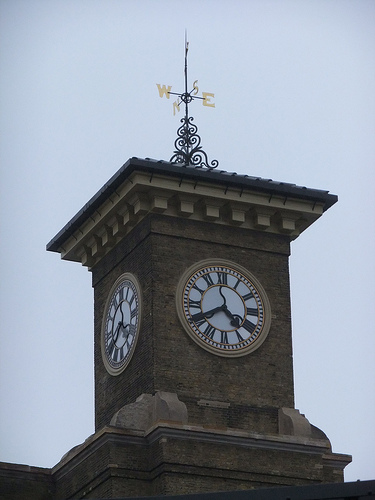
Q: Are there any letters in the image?
A: Yes, there are letters.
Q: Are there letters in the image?
A: Yes, there are letters.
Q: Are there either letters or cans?
A: Yes, there are letters.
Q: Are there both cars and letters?
A: No, there are letters but no cars.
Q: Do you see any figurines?
A: No, there are no figurines.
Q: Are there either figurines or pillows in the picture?
A: No, there are no figurines or pillows.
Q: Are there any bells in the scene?
A: No, there are no bells.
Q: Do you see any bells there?
A: No, there are no bells.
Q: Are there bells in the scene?
A: No, there are no bells.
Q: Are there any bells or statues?
A: No, there are no bells or statues.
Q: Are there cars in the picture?
A: No, there are no cars.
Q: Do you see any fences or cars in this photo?
A: No, there are no cars or fences.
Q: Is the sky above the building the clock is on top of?
A: Yes, the sky is above the building.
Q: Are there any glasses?
A: No, there are no glasses.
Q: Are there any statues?
A: No, there are no statues.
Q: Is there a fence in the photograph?
A: No, there are no fences.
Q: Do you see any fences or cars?
A: No, there are no fences or cars.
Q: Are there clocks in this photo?
A: Yes, there is a clock.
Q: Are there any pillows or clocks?
A: Yes, there is a clock.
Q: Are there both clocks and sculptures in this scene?
A: No, there is a clock but no sculptures.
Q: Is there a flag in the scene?
A: No, there are no flags.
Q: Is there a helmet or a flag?
A: No, there are no flags or helmets.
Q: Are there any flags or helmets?
A: No, there are no flags or helmets.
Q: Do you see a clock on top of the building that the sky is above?
A: Yes, there is a clock on top of the building.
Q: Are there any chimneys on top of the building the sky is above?
A: No, there is a clock on top of the building.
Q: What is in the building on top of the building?
A: The clock is in the clock tower.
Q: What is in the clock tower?
A: The clock is in the clock tower.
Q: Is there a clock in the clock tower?
A: Yes, there is a clock in the clock tower.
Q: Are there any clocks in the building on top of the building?
A: Yes, there is a clock in the clock tower.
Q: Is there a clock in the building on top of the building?
A: Yes, there is a clock in the clock tower.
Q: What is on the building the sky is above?
A: The clock is on the building.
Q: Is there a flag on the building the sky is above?
A: No, there is a clock on the building.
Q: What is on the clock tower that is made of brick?
A: The clock is on the clock tower.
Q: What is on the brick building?
A: The clock is on the clock tower.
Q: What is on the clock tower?
A: The clock is on the clock tower.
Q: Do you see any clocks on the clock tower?
A: Yes, there is a clock on the clock tower.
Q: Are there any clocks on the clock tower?
A: Yes, there is a clock on the clock tower.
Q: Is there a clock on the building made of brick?
A: Yes, there is a clock on the clock tower.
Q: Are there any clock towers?
A: Yes, there is a clock tower.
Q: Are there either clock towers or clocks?
A: Yes, there is a clock tower.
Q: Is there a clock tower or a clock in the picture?
A: Yes, there is a clock tower.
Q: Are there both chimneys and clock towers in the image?
A: No, there is a clock tower but no chimneys.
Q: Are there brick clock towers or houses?
A: Yes, there is a brick clock tower.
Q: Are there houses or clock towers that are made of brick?
A: Yes, the clock tower is made of brick.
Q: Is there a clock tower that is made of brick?
A: Yes, there is a clock tower that is made of brick.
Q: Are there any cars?
A: No, there are no cars.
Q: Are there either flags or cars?
A: No, there are no cars or flags.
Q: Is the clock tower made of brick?
A: Yes, the clock tower is made of brick.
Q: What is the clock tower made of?
A: The clock tower is made of brick.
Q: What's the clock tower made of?
A: The clock tower is made of brick.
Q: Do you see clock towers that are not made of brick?
A: No, there is a clock tower but it is made of brick.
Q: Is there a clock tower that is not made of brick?
A: No, there is a clock tower but it is made of brick.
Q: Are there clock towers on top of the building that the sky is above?
A: Yes, there is a clock tower on top of the building.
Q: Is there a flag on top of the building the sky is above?
A: No, there is a clock tower on top of the building.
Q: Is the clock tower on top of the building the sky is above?
A: Yes, the clock tower is on top of the building.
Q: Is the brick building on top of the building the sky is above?
A: Yes, the clock tower is on top of the building.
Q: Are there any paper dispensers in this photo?
A: No, there are no paper dispensers.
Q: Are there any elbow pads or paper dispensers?
A: No, there are no paper dispensers or elbow pads.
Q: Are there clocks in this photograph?
A: Yes, there is a clock.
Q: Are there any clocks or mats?
A: Yes, there is a clock.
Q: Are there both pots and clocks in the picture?
A: No, there is a clock but no pots.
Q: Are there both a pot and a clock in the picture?
A: No, there is a clock but no pots.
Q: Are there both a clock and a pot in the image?
A: No, there is a clock but no pots.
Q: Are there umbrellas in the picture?
A: No, there are no umbrellas.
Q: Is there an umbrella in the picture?
A: No, there are no umbrellas.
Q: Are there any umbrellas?
A: No, there are no umbrellas.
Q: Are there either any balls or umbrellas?
A: No, there are no umbrellas or balls.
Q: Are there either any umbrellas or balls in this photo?
A: No, there are no umbrellas or balls.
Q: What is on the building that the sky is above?
A: The clock is on the building.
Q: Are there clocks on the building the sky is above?
A: Yes, there is a clock on the building.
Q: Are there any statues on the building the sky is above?
A: No, there is a clock on the building.